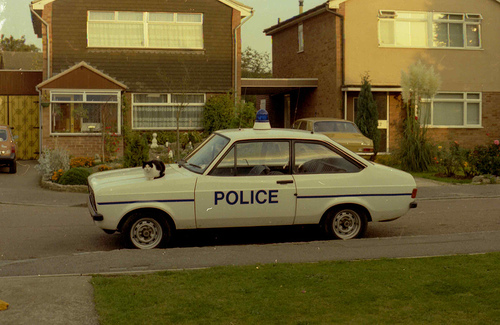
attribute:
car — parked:
[85, 125, 418, 246]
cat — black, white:
[140, 156, 167, 181]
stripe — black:
[99, 188, 416, 205]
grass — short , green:
[97, 260, 499, 323]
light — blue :
[244, 101, 283, 135]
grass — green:
[160, 277, 455, 319]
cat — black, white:
[138, 155, 169, 185]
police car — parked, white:
[76, 107, 433, 247]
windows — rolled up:
[207, 138, 365, 177]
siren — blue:
[251, 107, 272, 128]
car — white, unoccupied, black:
[83, 106, 418, 248]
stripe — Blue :
[94, 185, 423, 210]